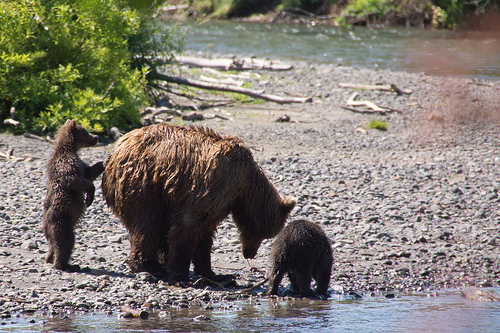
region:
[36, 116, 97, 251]
the bear is on two legs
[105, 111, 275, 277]
the bear is brown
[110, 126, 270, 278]
the bear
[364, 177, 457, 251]
rocks in the dirt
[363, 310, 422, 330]
the water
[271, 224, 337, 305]
an animal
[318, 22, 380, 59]
the water is green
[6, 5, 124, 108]
a green bush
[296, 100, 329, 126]
the dirt is brown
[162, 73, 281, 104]
a tree trunk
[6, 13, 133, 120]
a bush on the ground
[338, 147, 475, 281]
rocks on the ground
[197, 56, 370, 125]
sticks on the ground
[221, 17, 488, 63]
water next to the dirt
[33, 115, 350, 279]
bears near the water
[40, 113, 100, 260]
a baby bear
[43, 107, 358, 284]
a large bear with two baby bears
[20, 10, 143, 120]
leaves on a bush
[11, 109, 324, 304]
brown bears on the shore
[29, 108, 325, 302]
brown bears on the shore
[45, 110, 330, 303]
brown bears on the shore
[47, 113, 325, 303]
brown bears on the shore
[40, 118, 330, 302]
brown bears on the shore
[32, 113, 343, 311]
brown bears on the shore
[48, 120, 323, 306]
brown bears on the shore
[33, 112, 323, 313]
brown bears on the shore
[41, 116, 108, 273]
A bear standing up.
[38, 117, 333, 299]
A mama and baby bears.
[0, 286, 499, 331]
A little water on the shore.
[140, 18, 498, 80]
A river with rushing water.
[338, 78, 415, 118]
Branches on the ground.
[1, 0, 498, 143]
Bushes next to a river.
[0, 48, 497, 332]
Rocks on the shore.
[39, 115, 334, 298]
Bears by a river.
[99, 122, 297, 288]
A big wet bear.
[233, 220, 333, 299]
The back of a baby bear.